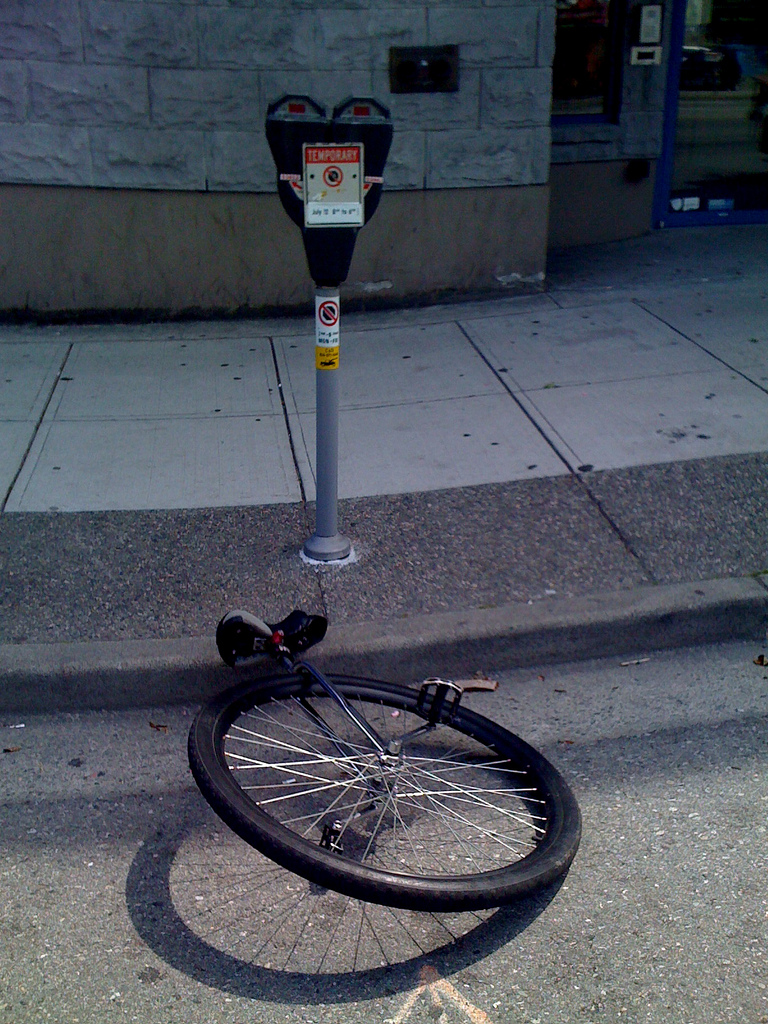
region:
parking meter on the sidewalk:
[271, 83, 376, 562]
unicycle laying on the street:
[183, 581, 575, 911]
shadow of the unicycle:
[100, 744, 594, 1002]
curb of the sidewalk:
[5, 580, 766, 719]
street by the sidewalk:
[5, 639, 766, 1018]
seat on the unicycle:
[226, 600, 339, 662]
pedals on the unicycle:
[298, 649, 473, 869]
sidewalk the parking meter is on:
[10, 323, 767, 648]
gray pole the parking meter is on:
[295, 292, 358, 569]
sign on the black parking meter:
[307, 139, 361, 223]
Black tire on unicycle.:
[183, 674, 531, 958]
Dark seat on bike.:
[195, 599, 316, 652]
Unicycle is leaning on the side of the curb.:
[149, 595, 557, 960]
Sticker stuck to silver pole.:
[311, 294, 350, 383]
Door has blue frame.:
[659, 31, 753, 248]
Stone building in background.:
[56, 26, 543, 170]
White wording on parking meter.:
[304, 145, 365, 166]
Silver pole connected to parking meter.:
[306, 286, 350, 584]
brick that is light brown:
[46, 192, 208, 310]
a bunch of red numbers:
[272, 106, 315, 116]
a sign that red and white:
[298, 144, 370, 203]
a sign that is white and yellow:
[309, 297, 359, 373]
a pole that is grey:
[272, 372, 383, 529]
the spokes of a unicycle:
[228, 712, 304, 775]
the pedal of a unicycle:
[397, 657, 500, 720]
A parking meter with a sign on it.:
[263, 95, 394, 284]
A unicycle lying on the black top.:
[177, 600, 591, 922]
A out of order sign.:
[296, 137, 365, 230]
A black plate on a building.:
[386, 42, 463, 92]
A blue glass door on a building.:
[656, 1, 762, 228]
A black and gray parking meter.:
[268, 93, 390, 563]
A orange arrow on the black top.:
[382, 961, 505, 1015]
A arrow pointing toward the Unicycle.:
[373, 960, 500, 1017]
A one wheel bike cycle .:
[179, 599, 587, 929]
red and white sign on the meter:
[292, 133, 384, 251]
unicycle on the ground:
[185, 598, 604, 928]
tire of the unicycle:
[181, 664, 583, 932]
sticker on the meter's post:
[303, 290, 358, 382]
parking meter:
[256, 83, 424, 587]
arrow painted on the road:
[378, 959, 486, 1016]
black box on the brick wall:
[382, 27, 501, 136]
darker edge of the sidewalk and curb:
[5, 439, 766, 707]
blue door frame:
[660, 8, 763, 254]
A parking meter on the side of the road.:
[246, 99, 375, 564]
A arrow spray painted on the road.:
[379, 956, 479, 1019]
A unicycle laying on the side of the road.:
[156, 574, 615, 909]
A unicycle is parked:
[181, 607, 585, 914]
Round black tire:
[180, 664, 584, 918]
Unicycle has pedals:
[184, 603, 584, 913]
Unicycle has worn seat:
[180, 603, 584, 916]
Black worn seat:
[213, 604, 331, 676]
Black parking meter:
[260, 88, 400, 563]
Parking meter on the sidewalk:
[6, 89, 765, 713]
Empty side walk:
[0, 278, 764, 706]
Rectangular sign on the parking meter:
[300, 139, 366, 228]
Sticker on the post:
[298, 285, 351, 561]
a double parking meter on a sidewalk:
[239, 80, 410, 602]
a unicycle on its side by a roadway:
[160, 606, 602, 920]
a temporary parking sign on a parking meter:
[294, 138, 379, 232]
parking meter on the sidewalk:
[255, 85, 399, 579]